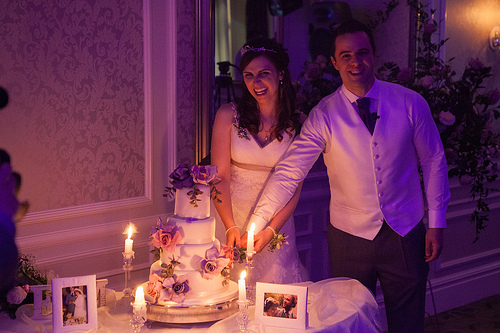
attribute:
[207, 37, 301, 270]
bride — smiling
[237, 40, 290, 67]
tiara — silver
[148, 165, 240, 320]
cake — four tiered, small, tiered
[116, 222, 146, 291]
candle — white, lit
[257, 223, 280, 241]
wrist band — white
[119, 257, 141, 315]
candle stick — glass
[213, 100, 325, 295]
wedding dress — white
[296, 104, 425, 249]
vest — white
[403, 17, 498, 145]
mirror — large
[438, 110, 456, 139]
flower — rose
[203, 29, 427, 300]
couple — married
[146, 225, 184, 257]
rose — pink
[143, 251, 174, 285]
leaves — green